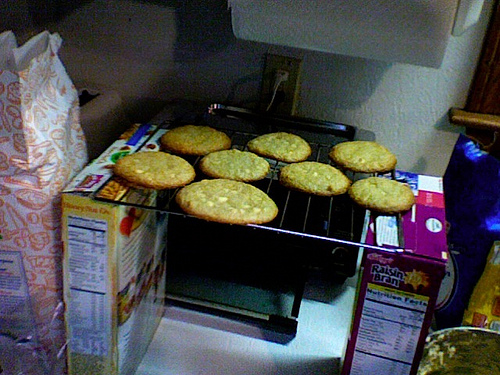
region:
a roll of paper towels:
[230, 7, 451, 72]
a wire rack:
[105, 96, 420, 266]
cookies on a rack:
[116, 110, 407, 230]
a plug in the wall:
[268, 56, 291, 92]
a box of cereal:
[358, 193, 408, 373]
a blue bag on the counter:
[440, 150, 497, 288]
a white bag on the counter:
[5, 37, 86, 373]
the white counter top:
[156, 329, 282, 349]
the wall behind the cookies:
[91, 17, 255, 88]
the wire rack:
[293, 198, 353, 240]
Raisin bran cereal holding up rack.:
[359, 215, 438, 344]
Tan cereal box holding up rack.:
[79, 173, 135, 266]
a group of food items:
[114, 84, 450, 232]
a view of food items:
[92, 90, 447, 273]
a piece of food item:
[163, 150, 298, 254]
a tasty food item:
[103, 95, 342, 231]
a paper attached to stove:
[361, 252, 414, 371]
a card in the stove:
[396, 180, 460, 285]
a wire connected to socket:
[197, 33, 334, 118]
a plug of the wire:
[251, 57, 326, 95]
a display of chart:
[54, 224, 119, 364]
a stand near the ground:
[183, 277, 324, 352]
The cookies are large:
[105, 127, 222, 237]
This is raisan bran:
[366, 259, 422, 314]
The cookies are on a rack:
[141, 98, 391, 261]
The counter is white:
[168, 325, 210, 367]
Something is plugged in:
[259, 56, 330, 121]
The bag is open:
[5, 16, 90, 122]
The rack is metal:
[253, 172, 357, 263]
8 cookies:
[109, 85, 457, 284]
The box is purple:
[399, 217, 473, 289]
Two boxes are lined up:
[41, 120, 447, 341]